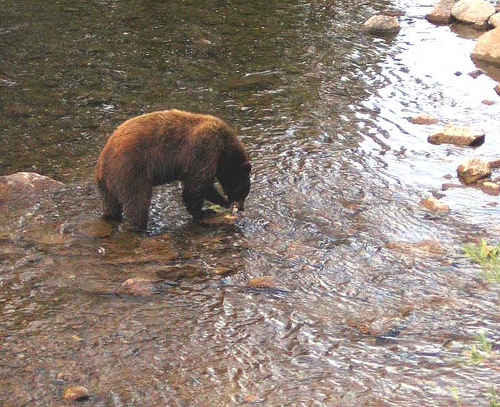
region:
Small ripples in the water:
[287, 122, 382, 327]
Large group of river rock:
[363, 6, 495, 70]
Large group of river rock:
[405, 103, 497, 220]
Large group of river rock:
[314, 225, 471, 350]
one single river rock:
[0, 165, 67, 259]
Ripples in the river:
[122, 305, 324, 405]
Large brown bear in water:
[66, 70, 268, 260]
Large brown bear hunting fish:
[85, 84, 272, 277]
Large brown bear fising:
[80, 77, 260, 274]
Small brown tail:
[92, 150, 109, 213]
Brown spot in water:
[92, 107, 256, 235]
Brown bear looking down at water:
[93, 105, 253, 241]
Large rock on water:
[425, 122, 481, 147]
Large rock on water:
[61, 377, 86, 398]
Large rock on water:
[360, 10, 400, 32]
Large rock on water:
[453, 152, 492, 184]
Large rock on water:
[419, 195, 448, 211]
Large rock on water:
[0, 173, 113, 248]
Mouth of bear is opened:
[225, 196, 245, 217]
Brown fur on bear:
[93, 107, 250, 237]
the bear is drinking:
[82, 97, 323, 299]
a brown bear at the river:
[112, 95, 298, 270]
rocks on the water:
[367, 5, 495, 189]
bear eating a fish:
[86, 91, 266, 253]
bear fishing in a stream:
[47, 83, 274, 277]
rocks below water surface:
[96, 225, 316, 308]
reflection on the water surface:
[355, 0, 498, 238]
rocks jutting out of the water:
[422, 6, 498, 76]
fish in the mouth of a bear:
[213, 200, 248, 220]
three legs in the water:
[93, 171, 213, 238]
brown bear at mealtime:
[38, 88, 270, 258]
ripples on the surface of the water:
[103, 208, 384, 393]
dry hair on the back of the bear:
[97, 105, 231, 162]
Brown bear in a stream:
[55, 92, 269, 312]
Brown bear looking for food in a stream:
[91, 100, 311, 217]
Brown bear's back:
[110, 106, 257, 148]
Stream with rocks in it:
[20, 230, 477, 397]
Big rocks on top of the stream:
[350, 0, 492, 120]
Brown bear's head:
[210, 135, 252, 215]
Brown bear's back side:
[35, 122, 170, 187]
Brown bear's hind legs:
[70, 190, 172, 265]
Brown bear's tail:
[91, 153, 113, 210]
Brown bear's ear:
[225, 151, 256, 184]